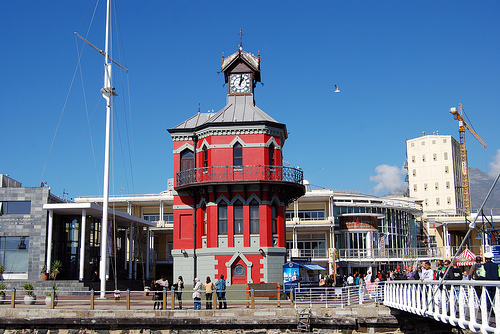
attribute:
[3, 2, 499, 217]
sky — clear, blue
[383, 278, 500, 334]
guard rail — white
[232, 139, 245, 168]
windows — large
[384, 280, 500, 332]
post — wooden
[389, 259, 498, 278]
people — standing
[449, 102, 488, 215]
crane — orange, metal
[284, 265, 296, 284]
sign — blue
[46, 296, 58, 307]
pot — grey, gray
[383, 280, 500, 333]
bridge — metal, white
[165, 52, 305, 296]
building — red, round, blue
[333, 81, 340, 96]
bird — flying, red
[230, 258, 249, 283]
door — shut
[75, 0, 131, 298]
pole — white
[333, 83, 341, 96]
sea gull — flying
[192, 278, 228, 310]
tourists — standing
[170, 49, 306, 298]
clocktower — red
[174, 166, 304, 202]
balcony — black